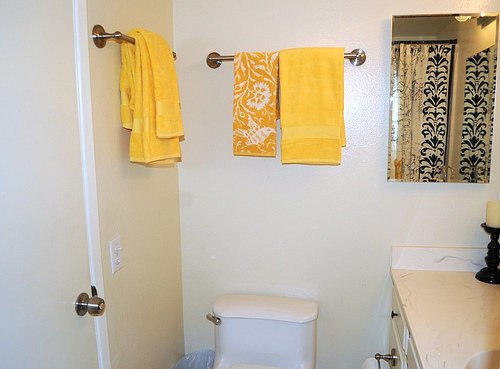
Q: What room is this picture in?
A: It is at the bathroom.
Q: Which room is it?
A: It is a bathroom.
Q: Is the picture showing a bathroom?
A: Yes, it is showing a bathroom.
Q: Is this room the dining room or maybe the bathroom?
A: It is the bathroom.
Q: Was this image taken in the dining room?
A: No, the picture was taken in the bathroom.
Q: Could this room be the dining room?
A: No, it is the bathroom.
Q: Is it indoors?
A: Yes, it is indoors.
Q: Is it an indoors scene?
A: Yes, it is indoors.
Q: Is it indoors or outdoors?
A: It is indoors.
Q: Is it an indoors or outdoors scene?
A: It is indoors.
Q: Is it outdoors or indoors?
A: It is indoors.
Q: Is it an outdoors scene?
A: No, it is indoors.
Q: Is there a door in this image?
A: Yes, there is a door.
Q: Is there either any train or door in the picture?
A: Yes, there is a door.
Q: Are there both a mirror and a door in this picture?
A: Yes, there are both a door and a mirror.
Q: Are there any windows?
A: No, there are no windows.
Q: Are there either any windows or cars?
A: No, there are no windows or cars.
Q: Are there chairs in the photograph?
A: No, there are no chairs.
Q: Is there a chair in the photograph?
A: No, there are no chairs.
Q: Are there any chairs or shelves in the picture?
A: No, there are no chairs or shelves.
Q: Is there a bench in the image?
A: No, there are no benches.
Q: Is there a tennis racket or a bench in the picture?
A: No, there are no benches or rackets.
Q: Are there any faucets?
A: No, there are no faucets.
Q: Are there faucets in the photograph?
A: No, there are no faucets.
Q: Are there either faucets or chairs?
A: No, there are no faucets or chairs.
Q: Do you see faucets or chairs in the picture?
A: No, there are no faucets or chairs.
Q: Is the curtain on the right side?
A: Yes, the curtain is on the right of the image.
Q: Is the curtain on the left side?
A: No, the curtain is on the right of the image.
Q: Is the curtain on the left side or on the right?
A: The curtain is on the right of the image.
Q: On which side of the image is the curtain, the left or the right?
A: The curtain is on the right of the image.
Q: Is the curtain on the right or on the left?
A: The curtain is on the right of the image.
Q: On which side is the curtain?
A: The curtain is on the right of the image.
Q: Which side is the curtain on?
A: The curtain is on the right of the image.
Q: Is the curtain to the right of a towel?
A: Yes, the curtain is to the right of a towel.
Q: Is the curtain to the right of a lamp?
A: No, the curtain is to the right of a towel.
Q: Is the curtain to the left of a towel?
A: No, the curtain is to the right of a towel.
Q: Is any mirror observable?
A: Yes, there is a mirror.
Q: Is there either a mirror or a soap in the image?
A: Yes, there is a mirror.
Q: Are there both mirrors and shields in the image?
A: No, there is a mirror but no shields.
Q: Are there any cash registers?
A: No, there are no cash registers.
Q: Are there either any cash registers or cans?
A: No, there are no cash registers or cans.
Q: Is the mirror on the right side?
A: Yes, the mirror is on the right of the image.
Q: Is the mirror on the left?
A: No, the mirror is on the right of the image.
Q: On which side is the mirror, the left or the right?
A: The mirror is on the right of the image.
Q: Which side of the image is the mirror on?
A: The mirror is on the right of the image.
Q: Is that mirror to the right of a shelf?
A: No, the mirror is to the right of the towel.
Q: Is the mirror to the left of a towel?
A: No, the mirror is to the right of a towel.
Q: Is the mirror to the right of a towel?
A: Yes, the mirror is to the right of a towel.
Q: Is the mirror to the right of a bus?
A: No, the mirror is to the right of a towel.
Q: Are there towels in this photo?
A: Yes, there is a towel.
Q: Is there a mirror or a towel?
A: Yes, there is a towel.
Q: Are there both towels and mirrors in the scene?
A: Yes, there are both a towel and a mirror.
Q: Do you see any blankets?
A: No, there are no blankets.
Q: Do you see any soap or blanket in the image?
A: No, there are no blankets or soaps.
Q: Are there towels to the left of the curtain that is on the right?
A: Yes, there is a towel to the left of the curtain.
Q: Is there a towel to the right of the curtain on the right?
A: No, the towel is to the left of the curtain.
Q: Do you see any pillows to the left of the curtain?
A: No, there is a towel to the left of the curtain.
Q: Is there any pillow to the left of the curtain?
A: No, there is a towel to the left of the curtain.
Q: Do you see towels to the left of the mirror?
A: Yes, there is a towel to the left of the mirror.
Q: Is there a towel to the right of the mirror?
A: No, the towel is to the left of the mirror.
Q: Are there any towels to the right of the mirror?
A: No, the towel is to the left of the mirror.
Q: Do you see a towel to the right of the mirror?
A: No, the towel is to the left of the mirror.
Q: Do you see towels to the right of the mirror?
A: No, the towel is to the left of the mirror.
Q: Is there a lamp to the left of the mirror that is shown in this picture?
A: No, there is a towel to the left of the mirror.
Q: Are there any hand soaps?
A: No, there are no hand soaps.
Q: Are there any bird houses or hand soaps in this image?
A: No, there are no hand soaps or bird houses.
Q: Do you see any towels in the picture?
A: Yes, there is a towel.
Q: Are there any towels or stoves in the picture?
A: Yes, there is a towel.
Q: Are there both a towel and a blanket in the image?
A: No, there is a towel but no blankets.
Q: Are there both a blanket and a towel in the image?
A: No, there is a towel but no blankets.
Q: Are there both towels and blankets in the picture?
A: No, there is a towel but no blankets.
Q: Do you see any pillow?
A: No, there are no pillows.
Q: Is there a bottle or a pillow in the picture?
A: No, there are no pillows or bottles.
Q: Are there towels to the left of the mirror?
A: Yes, there is a towel to the left of the mirror.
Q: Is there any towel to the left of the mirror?
A: Yes, there is a towel to the left of the mirror.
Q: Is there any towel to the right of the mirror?
A: No, the towel is to the left of the mirror.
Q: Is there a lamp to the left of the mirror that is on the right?
A: No, there is a towel to the left of the mirror.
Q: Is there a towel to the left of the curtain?
A: Yes, there is a towel to the left of the curtain.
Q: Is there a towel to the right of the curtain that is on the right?
A: No, the towel is to the left of the curtain.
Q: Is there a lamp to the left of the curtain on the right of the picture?
A: No, there is a towel to the left of the curtain.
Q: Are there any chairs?
A: No, there are no chairs.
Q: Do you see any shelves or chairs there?
A: No, there are no chairs or shelves.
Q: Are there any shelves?
A: No, there are no shelves.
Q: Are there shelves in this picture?
A: No, there are no shelves.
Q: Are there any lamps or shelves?
A: No, there are no shelves or lamps.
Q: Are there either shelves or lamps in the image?
A: No, there are no shelves or lamps.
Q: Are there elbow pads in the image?
A: No, there are no elbow pads.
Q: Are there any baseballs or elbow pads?
A: No, there are no elbow pads or baseballs.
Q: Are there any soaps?
A: No, there are no soaps.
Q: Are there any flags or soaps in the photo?
A: No, there are no soaps or flags.